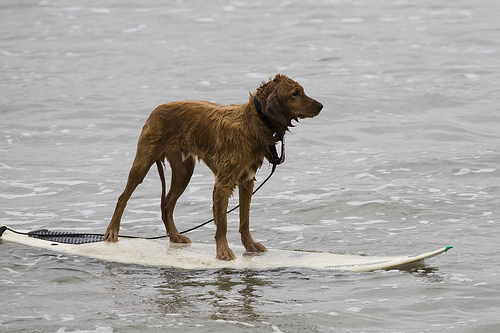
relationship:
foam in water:
[281, 188, 346, 202] [0, 0, 496, 330]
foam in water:
[337, 302, 364, 314] [0, 0, 496, 330]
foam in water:
[453, 162, 497, 179] [0, 0, 496, 330]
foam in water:
[17, 259, 39, 271] [0, 0, 496, 330]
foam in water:
[344, 196, 390, 211] [0, 0, 496, 330]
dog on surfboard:
[100, 64, 305, 256] [9, 169, 474, 326]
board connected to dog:
[0, 223, 458, 275] [100, 72, 328, 262]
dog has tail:
[100, 72, 328, 262] [154, 160, 168, 204]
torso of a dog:
[136, 95, 258, 169] [100, 72, 328, 262]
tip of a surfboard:
[443, 240, 454, 257] [1, 218, 453, 269]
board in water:
[0, 223, 458, 275] [0, 0, 496, 330]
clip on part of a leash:
[268, 127, 290, 164] [32, 140, 287, 238]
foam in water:
[414, 217, 441, 229] [0, 0, 496, 330]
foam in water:
[446, 167, 493, 179] [17, 5, 459, 56]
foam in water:
[295, 185, 348, 205] [17, 5, 459, 56]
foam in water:
[350, 161, 385, 186] [17, 5, 459, 56]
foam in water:
[338, 297, 377, 319] [17, 5, 459, 56]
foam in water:
[439, 262, 484, 292] [17, 5, 459, 56]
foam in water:
[268, 322, 280, 331] [0, 272, 498, 331]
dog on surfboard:
[100, 72, 328, 262] [40, 175, 459, 292]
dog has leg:
[100, 72, 328, 262] [97, 145, 157, 245]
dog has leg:
[100, 72, 328, 262] [157, 162, 199, 246]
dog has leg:
[100, 72, 328, 262] [205, 173, 238, 263]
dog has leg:
[100, 72, 328, 262] [235, 185, 269, 256]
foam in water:
[55, 322, 113, 331] [0, 0, 496, 330]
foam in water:
[269, 213, 316, 235] [145, 274, 417, 326]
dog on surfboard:
[100, 72, 328, 262] [2, 221, 454, 273]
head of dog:
[260, 72, 353, 143] [77, 62, 284, 267]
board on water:
[0, 223, 458, 275] [0, 0, 496, 330]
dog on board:
[100, 72, 328, 262] [0, 211, 465, 279]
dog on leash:
[100, 72, 328, 262] [124, 122, 292, 246]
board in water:
[0, 223, 458, 275] [4, 248, 154, 330]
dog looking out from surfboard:
[100, 72, 328, 262] [4, 214, 468, 285]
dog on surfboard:
[100, 72, 328, 262] [4, 214, 468, 285]